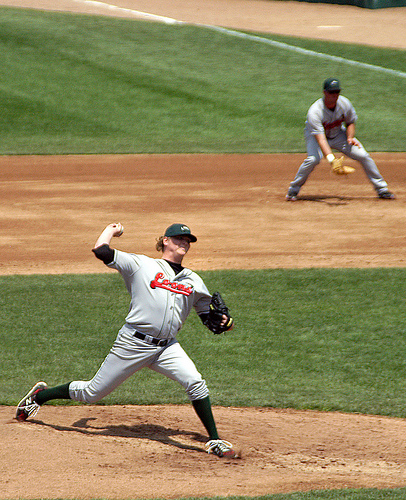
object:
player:
[283, 71, 395, 201]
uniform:
[38, 247, 234, 436]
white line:
[84, 1, 404, 80]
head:
[161, 222, 192, 258]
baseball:
[112, 224, 124, 237]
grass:
[0, 264, 406, 420]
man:
[13, 218, 240, 463]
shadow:
[25, 416, 213, 455]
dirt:
[1, 402, 404, 497]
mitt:
[328, 155, 354, 175]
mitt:
[205, 291, 234, 335]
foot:
[207, 439, 236, 462]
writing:
[150, 272, 193, 300]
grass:
[0, 4, 404, 154]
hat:
[164, 222, 198, 243]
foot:
[13, 380, 51, 424]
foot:
[284, 192, 298, 202]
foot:
[378, 189, 396, 200]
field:
[1, 0, 401, 497]